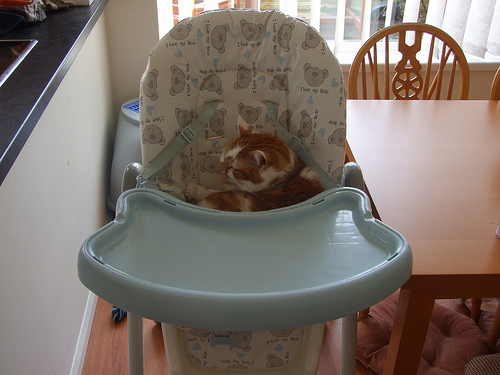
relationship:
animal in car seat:
[196, 113, 325, 212] [134, 7, 347, 374]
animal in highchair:
[196, 113, 325, 212] [77, 8, 412, 369]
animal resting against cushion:
[196, 113, 325, 212] [137, 9, 347, 369]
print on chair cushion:
[234, 64, 254, 96] [134, 10, 351, 132]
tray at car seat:
[80, 180, 412, 326] [134, 7, 347, 374]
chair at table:
[341, 24, 471, 101] [417, 130, 471, 187]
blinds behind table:
[151, 0, 496, 64] [346, 94, 471, 227]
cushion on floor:
[364, 287, 483, 369] [93, 299, 499, 369]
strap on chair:
[128, 97, 223, 184] [74, 8, 412, 365]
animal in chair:
[196, 113, 325, 212] [74, 8, 412, 365]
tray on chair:
[80, 187, 412, 296] [130, 20, 375, 364]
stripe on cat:
[218, 147, 285, 189] [135, 56, 413, 277]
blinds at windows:
[164, 0, 498, 60] [163, 0, 498, 62]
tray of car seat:
[80, 180, 412, 326] [134, 7, 347, 374]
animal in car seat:
[196, 113, 325, 212] [108, 7, 371, 296]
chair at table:
[346, 22, 476, 99] [337, 92, 498, 371]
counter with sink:
[2, 0, 109, 187] [0, 35, 37, 88]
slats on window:
[157, 56, 199, 86] [156, 0, 493, 79]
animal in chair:
[118, 91, 358, 249] [328, 36, 466, 331]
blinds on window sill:
[311, 2, 370, 37] [333, 37, 355, 59]